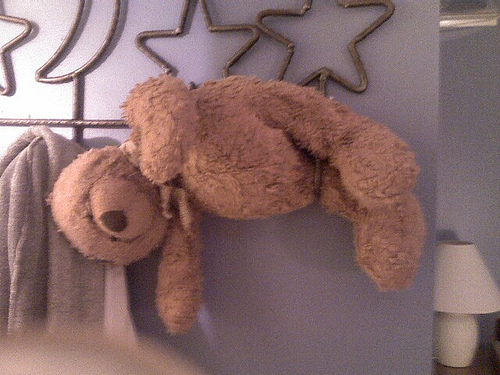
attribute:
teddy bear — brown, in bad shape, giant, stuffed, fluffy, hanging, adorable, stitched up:
[43, 73, 428, 339]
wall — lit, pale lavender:
[1, 0, 440, 373]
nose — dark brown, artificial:
[100, 210, 129, 233]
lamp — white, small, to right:
[431, 241, 498, 368]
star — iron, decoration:
[254, 0, 395, 93]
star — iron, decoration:
[136, 0, 262, 77]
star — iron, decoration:
[0, 1, 33, 97]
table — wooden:
[431, 341, 499, 374]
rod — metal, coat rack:
[0, 0, 394, 200]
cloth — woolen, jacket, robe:
[0, 125, 106, 342]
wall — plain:
[432, 28, 499, 344]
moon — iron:
[34, 1, 122, 84]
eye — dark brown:
[87, 213, 94, 221]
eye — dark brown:
[108, 234, 115, 242]